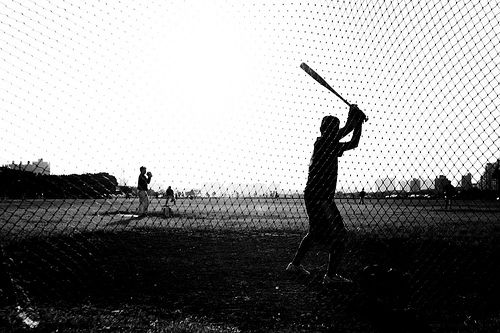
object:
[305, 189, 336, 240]
tan colored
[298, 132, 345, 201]
boy's tshirt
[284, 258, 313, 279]
shoes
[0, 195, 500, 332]
baseball diamond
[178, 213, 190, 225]
holes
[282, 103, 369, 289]
kid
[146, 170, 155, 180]
baseball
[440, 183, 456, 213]
baseman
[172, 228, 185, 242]
small holes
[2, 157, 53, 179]
building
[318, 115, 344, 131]
hat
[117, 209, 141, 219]
diamond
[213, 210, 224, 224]
holes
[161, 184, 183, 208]
outfielder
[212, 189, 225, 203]
holes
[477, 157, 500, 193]
buildings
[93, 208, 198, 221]
pitchers mound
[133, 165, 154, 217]
pitcher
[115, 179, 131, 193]
holes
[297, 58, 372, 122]
baseball bat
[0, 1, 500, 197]
sky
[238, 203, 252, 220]
holes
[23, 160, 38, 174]
holes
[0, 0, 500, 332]
fence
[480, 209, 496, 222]
holes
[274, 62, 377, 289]
baseball game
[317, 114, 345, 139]
head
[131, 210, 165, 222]
base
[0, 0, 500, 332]
photo